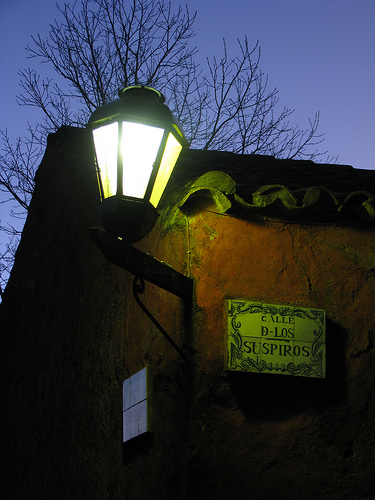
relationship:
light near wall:
[86, 84, 191, 241] [1, 124, 188, 499]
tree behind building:
[1, 0, 338, 302] [1, 126, 374, 500]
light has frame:
[86, 84, 191, 241] [86, 85, 187, 243]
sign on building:
[225, 298, 329, 380] [1, 126, 374, 500]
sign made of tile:
[225, 298, 329, 380] [222, 298, 329, 381]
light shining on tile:
[86, 84, 191, 241] [222, 298, 329, 381]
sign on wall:
[225, 298, 329, 380] [185, 197, 374, 499]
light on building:
[86, 84, 191, 241] [1, 126, 374, 500]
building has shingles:
[1, 126, 374, 500] [44, 125, 375, 223]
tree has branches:
[1, 0, 338, 302] [1, 2, 326, 296]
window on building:
[118, 365, 152, 447] [1, 126, 374, 500]